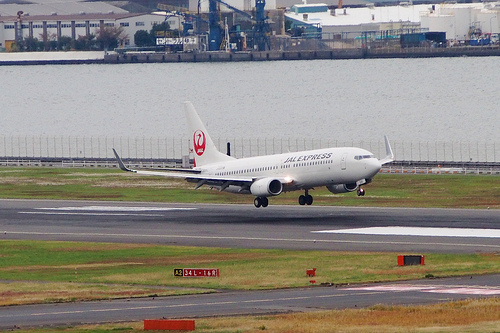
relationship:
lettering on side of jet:
[282, 148, 335, 164] [107, 98, 398, 215]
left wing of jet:
[331, 132, 397, 170] [107, 98, 398, 215]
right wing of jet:
[105, 145, 295, 195] [107, 98, 398, 215]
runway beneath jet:
[4, 185, 498, 256] [107, 98, 398, 215]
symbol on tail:
[190, 130, 209, 156] [178, 97, 225, 168]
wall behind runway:
[1, 53, 499, 179] [4, 185, 498, 256]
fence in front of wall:
[1, 130, 500, 176] [1, 53, 499, 179]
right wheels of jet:
[251, 196, 272, 210] [107, 98, 398, 215]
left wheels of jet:
[296, 194, 313, 208] [107, 98, 398, 215]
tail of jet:
[178, 97, 225, 168] [107, 98, 398, 215]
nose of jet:
[357, 158, 390, 179] [107, 98, 398, 215]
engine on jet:
[248, 175, 285, 198] [107, 98, 398, 215]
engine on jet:
[326, 179, 360, 196] [107, 98, 398, 215]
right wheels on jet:
[251, 196, 272, 210] [107, 98, 398, 215]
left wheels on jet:
[296, 194, 313, 208] [107, 98, 398, 215]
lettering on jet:
[282, 148, 335, 164] [107, 98, 398, 215]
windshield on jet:
[354, 153, 377, 160] [107, 98, 398, 215]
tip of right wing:
[109, 147, 132, 171] [105, 145, 295, 195]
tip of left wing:
[382, 133, 396, 158] [331, 132, 397, 170]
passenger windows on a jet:
[208, 158, 335, 174] [107, 98, 398, 215]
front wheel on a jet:
[358, 189, 368, 198] [107, 98, 398, 215]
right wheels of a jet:
[251, 196, 272, 210] [107, 98, 398, 215]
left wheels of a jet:
[296, 194, 313, 208] [107, 98, 398, 215]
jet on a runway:
[107, 98, 398, 215] [4, 185, 498, 256]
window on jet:
[330, 159, 333, 164] [107, 98, 398, 215]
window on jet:
[292, 163, 296, 169] [107, 98, 398, 215]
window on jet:
[288, 163, 290, 167] [107, 98, 398, 215]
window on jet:
[267, 166, 271, 172] [107, 98, 398, 215]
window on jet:
[256, 168, 259, 171] [107, 98, 398, 215]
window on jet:
[249, 169, 251, 172] [107, 98, 398, 215]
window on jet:
[312, 162, 315, 166] [107, 98, 398, 215]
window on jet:
[302, 162, 306, 167] [107, 98, 398, 215]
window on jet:
[236, 169, 238, 173] [107, 98, 398, 215]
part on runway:
[241, 184, 284, 214] [4, 185, 498, 256]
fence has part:
[1, 130, 500, 176] [21, 150, 66, 171]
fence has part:
[1, 130, 500, 176] [393, 148, 434, 158]